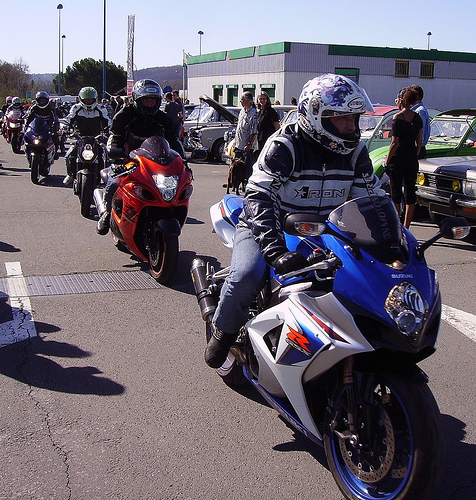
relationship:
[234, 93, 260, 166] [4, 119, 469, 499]
person in street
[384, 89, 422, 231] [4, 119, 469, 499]
woman in street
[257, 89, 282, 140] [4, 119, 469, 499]
person in street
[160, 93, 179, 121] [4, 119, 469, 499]
person in street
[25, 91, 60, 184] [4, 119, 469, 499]
person in street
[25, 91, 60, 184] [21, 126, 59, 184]
person on motorcycle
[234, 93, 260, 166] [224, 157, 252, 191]
person with dog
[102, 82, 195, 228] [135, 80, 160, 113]
person wearing helmet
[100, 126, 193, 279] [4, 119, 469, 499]
motorcycle on street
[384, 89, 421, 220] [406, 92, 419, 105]
woman with ponytail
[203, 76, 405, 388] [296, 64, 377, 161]
person wearing helmet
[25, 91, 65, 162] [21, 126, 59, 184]
person riding a motorcycle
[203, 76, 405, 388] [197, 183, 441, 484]
person riding a motorcycle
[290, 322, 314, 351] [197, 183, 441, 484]
lettering on motorcycle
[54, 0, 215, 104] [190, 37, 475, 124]
street lights behind building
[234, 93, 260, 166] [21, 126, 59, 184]
person standing next to motorcycle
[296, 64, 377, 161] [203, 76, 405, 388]
helmet on person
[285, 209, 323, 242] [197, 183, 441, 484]
side view mirror on motorcycle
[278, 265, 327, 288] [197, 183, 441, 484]
brake handle on motorcycle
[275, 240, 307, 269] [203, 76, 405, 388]
glove on person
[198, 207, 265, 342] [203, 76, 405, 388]
leg of person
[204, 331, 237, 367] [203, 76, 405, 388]
boot of person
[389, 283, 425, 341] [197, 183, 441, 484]
headlight on motorcycle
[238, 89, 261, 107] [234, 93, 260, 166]
head of person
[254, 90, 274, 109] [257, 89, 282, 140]
head of a person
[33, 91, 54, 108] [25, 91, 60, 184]
head of a person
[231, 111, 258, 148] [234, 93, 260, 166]
shirt of person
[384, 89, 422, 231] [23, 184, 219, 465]
woman in street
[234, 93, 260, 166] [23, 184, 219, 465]
person in street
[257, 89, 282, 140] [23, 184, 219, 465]
person in street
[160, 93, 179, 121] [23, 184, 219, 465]
person in street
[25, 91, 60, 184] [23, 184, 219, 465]
person in street